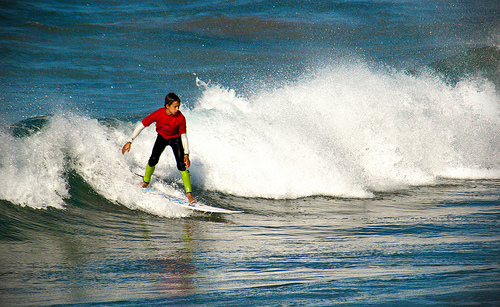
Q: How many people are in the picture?
A: One.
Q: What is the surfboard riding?
A: A wave.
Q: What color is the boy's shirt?
A: Red.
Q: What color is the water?
A: Blue.